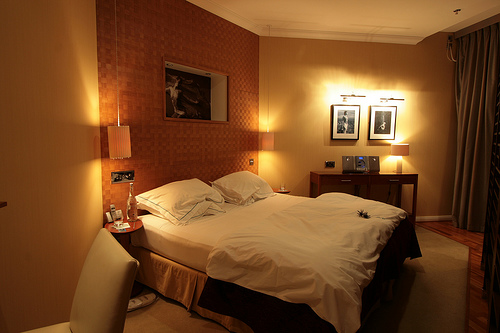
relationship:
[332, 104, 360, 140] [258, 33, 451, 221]
picture on wall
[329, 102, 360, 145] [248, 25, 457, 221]
picture hanging in wall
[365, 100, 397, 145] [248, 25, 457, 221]
picture hanging in wall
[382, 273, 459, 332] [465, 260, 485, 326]
carpet in floor